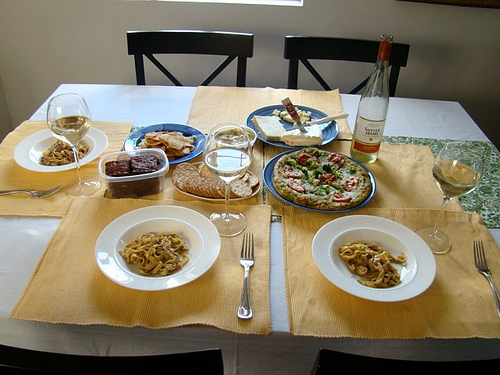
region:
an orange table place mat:
[9, 195, 95, 327]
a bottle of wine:
[349, 36, 395, 165]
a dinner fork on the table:
[238, 229, 256, 321]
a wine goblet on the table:
[46, 92, 101, 195]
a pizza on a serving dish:
[263, 150, 374, 215]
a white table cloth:
[390, 96, 486, 139]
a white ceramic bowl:
[92, 202, 219, 289]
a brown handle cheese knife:
[280, 95, 306, 135]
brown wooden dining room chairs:
[125, 28, 253, 85]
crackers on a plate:
[173, 163, 260, 200]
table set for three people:
[24, 9, 468, 346]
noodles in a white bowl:
[313, 216, 441, 320]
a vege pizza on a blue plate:
[271, 139, 366, 226]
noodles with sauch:
[81, 198, 233, 298]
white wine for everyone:
[345, 21, 400, 175]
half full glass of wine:
[419, 107, 491, 269]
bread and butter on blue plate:
[254, 75, 339, 154]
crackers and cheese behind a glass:
[173, 105, 297, 228]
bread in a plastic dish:
[100, 137, 179, 201]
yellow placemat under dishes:
[48, 177, 285, 332]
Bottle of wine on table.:
[346, 28, 408, 186]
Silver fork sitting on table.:
[466, 232, 497, 275]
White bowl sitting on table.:
[314, 227, 409, 309]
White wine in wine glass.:
[427, 155, 482, 206]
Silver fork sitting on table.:
[228, 235, 284, 329]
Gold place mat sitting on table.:
[276, 249, 390, 339]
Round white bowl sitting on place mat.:
[96, 221, 193, 263]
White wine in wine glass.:
[46, 107, 123, 157]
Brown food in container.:
[108, 153, 178, 190]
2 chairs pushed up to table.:
[110, 25, 417, 78]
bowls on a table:
[17, 61, 302, 361]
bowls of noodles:
[36, 48, 489, 205]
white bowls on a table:
[11, 66, 498, 333]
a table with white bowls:
[60, 86, 477, 329]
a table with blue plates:
[144, 66, 485, 267]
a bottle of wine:
[334, 23, 426, 188]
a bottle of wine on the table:
[326, 37, 413, 205]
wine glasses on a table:
[53, 56, 81, 214]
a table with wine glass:
[29, 81, 159, 245]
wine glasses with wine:
[72, 83, 112, 222]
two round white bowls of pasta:
[88, 204, 440, 305]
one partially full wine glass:
[42, 88, 103, 197]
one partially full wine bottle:
[355, 33, 395, 175]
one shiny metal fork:
[234, 229, 256, 326]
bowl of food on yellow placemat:
[13, 189, 275, 336]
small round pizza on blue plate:
[261, 143, 378, 213]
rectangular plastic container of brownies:
[96, 145, 173, 195]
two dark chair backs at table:
[121, 22, 408, 94]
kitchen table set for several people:
[8, 16, 495, 368]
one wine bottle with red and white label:
[343, 32, 396, 169]